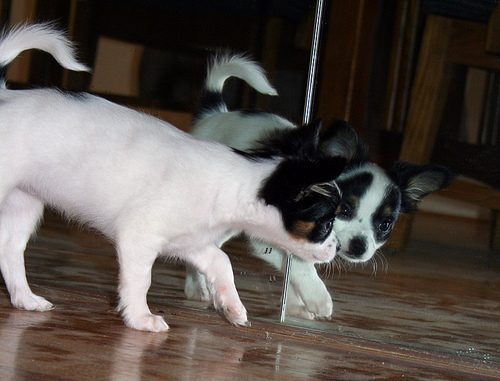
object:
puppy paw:
[119, 313, 170, 334]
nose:
[347, 236, 367, 257]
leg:
[115, 234, 172, 334]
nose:
[336, 241, 341, 252]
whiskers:
[339, 248, 394, 281]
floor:
[1, 198, 498, 378]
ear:
[267, 120, 322, 154]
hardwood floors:
[3, 227, 498, 375]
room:
[1, 0, 498, 380]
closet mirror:
[61, 0, 323, 100]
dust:
[21, 327, 97, 374]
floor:
[0, 286, 493, 379]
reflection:
[189, 48, 459, 324]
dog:
[0, 19, 352, 335]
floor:
[359, 279, 494, 369]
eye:
[326, 220, 335, 231]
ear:
[288, 152, 347, 187]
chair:
[379, 16, 496, 254]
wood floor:
[3, 334, 356, 380]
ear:
[315, 116, 361, 160]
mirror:
[280, 0, 500, 365]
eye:
[377, 221, 392, 234]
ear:
[402, 160, 467, 214]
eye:
[341, 204, 351, 217]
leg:
[0, 194, 55, 311]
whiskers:
[317, 255, 341, 281]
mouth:
[312, 254, 329, 262]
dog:
[183, 48, 458, 323]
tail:
[200, 49, 284, 113]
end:
[2, 22, 93, 73]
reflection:
[369, 280, 484, 325]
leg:
[187, 243, 250, 328]